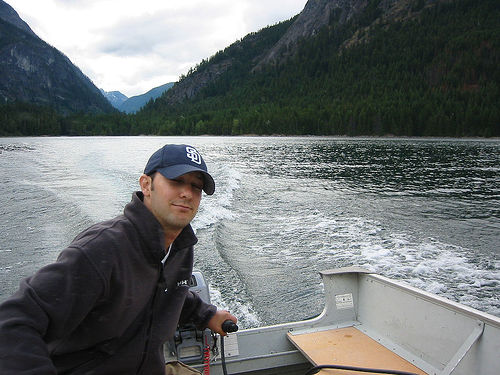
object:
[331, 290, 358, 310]
socket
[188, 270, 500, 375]
boat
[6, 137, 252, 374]
man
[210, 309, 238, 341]
hand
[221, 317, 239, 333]
object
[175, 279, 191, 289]
label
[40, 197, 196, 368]
jacket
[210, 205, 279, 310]
waves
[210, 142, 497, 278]
water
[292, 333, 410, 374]
bench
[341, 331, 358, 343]
spot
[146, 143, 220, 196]
cap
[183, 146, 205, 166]
logo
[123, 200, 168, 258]
collar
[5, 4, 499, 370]
photo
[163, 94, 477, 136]
trees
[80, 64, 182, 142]
valley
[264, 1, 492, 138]
mountains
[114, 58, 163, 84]
clouds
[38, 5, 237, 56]
sky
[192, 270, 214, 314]
engine